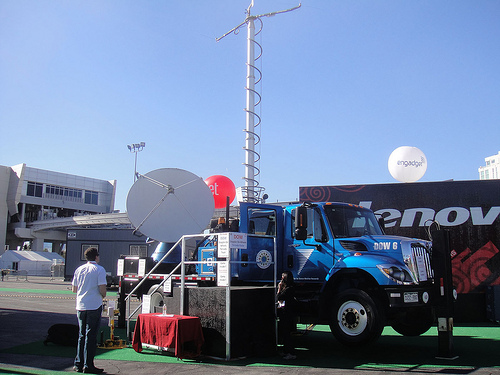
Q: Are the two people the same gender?
A: No, they are both male and female.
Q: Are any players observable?
A: No, there are no players.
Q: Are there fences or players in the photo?
A: No, there are no players or fences.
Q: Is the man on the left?
A: Yes, the man is on the left of the image.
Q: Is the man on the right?
A: No, the man is on the left of the image.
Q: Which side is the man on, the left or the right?
A: The man is on the left of the image.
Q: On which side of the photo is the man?
A: The man is on the left of the image.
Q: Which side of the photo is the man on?
A: The man is on the left of the image.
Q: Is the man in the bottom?
A: Yes, the man is in the bottom of the image.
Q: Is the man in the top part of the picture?
A: No, the man is in the bottom of the image.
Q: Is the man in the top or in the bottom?
A: The man is in the bottom of the image.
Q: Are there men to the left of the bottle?
A: Yes, there is a man to the left of the bottle.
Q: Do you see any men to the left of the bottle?
A: Yes, there is a man to the left of the bottle.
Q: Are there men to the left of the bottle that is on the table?
A: Yes, there is a man to the left of the bottle.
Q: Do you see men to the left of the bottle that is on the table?
A: Yes, there is a man to the left of the bottle.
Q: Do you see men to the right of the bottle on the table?
A: No, the man is to the left of the bottle.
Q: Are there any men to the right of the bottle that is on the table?
A: No, the man is to the left of the bottle.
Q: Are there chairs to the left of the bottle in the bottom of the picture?
A: No, there is a man to the left of the bottle.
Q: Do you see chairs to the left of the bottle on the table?
A: No, there is a man to the left of the bottle.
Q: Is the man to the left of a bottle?
A: Yes, the man is to the left of a bottle.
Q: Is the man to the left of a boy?
A: No, the man is to the left of a bottle.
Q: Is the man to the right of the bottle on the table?
A: No, the man is to the left of the bottle.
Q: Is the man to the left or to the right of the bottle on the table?
A: The man is to the left of the bottle.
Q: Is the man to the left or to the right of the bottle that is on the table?
A: The man is to the left of the bottle.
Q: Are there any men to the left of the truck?
A: Yes, there is a man to the left of the truck.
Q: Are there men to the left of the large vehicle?
A: Yes, there is a man to the left of the truck.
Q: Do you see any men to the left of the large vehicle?
A: Yes, there is a man to the left of the truck.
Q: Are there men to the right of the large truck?
A: No, the man is to the left of the truck.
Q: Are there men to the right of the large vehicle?
A: No, the man is to the left of the truck.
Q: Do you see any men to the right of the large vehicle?
A: No, the man is to the left of the truck.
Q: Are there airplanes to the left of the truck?
A: No, there is a man to the left of the truck.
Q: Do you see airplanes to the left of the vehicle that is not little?
A: No, there is a man to the left of the truck.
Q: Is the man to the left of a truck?
A: Yes, the man is to the left of a truck.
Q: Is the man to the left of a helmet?
A: No, the man is to the left of a truck.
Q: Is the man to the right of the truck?
A: No, the man is to the left of the truck.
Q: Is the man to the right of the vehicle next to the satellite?
A: No, the man is to the left of the truck.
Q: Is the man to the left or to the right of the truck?
A: The man is to the left of the truck.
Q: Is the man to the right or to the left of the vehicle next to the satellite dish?
A: The man is to the left of the truck.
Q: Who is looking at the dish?
A: The man is looking at the dish.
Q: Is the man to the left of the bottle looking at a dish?
A: Yes, the man is looking at a dish.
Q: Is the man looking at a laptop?
A: No, the man is looking at a dish.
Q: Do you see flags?
A: No, there are no flags.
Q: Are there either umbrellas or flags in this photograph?
A: No, there are no flags or umbrellas.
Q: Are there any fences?
A: No, there are no fences.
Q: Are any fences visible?
A: No, there are no fences.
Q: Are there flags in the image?
A: No, there are no flags.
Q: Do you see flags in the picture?
A: No, there are no flags.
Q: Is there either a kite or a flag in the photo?
A: No, there are no flags or kites.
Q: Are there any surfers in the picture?
A: No, there are no surfers.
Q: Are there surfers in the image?
A: No, there are no surfers.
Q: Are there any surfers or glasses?
A: No, there are no surfers or glasses.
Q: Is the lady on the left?
A: Yes, the lady is on the left of the image.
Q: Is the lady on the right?
A: No, the lady is on the left of the image.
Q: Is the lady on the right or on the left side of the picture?
A: The lady is on the left of the image.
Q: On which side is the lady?
A: The lady is on the left of the image.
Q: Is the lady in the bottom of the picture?
A: Yes, the lady is in the bottom of the image.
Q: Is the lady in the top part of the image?
A: No, the lady is in the bottom of the image.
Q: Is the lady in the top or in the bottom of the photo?
A: The lady is in the bottom of the image.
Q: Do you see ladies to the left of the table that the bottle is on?
A: Yes, there is a lady to the left of the table.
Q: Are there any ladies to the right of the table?
A: No, the lady is to the left of the table.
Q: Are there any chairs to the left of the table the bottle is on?
A: No, there is a lady to the left of the table.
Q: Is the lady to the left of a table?
A: Yes, the lady is to the left of a table.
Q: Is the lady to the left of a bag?
A: No, the lady is to the left of a table.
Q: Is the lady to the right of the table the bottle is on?
A: No, the lady is to the left of the table.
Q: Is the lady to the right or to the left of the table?
A: The lady is to the left of the table.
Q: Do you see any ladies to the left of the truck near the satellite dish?
A: Yes, there is a lady to the left of the truck.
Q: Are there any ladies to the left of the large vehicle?
A: Yes, there is a lady to the left of the truck.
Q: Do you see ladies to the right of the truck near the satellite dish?
A: No, the lady is to the left of the truck.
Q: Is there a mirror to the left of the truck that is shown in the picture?
A: No, there is a lady to the left of the truck.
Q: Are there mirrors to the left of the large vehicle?
A: No, there is a lady to the left of the truck.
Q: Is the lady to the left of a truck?
A: Yes, the lady is to the left of a truck.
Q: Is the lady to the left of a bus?
A: No, the lady is to the left of a truck.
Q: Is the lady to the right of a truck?
A: No, the lady is to the left of a truck.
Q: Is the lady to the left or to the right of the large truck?
A: The lady is to the left of the truck.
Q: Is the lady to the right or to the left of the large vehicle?
A: The lady is to the left of the truck.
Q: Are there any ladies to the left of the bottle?
A: Yes, there is a lady to the left of the bottle.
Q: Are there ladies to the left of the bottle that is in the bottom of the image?
A: Yes, there is a lady to the left of the bottle.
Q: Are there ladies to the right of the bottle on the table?
A: No, the lady is to the left of the bottle.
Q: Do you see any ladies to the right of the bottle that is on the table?
A: No, the lady is to the left of the bottle.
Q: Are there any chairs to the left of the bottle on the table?
A: No, there is a lady to the left of the bottle.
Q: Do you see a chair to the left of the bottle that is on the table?
A: No, there is a lady to the left of the bottle.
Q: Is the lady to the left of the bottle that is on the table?
A: Yes, the lady is to the left of the bottle.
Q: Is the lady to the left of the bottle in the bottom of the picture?
A: Yes, the lady is to the left of the bottle.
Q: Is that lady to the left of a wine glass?
A: No, the lady is to the left of the bottle.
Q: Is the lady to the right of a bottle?
A: No, the lady is to the left of a bottle.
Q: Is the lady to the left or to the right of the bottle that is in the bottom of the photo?
A: The lady is to the left of the bottle.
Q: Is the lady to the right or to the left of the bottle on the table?
A: The lady is to the left of the bottle.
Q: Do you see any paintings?
A: No, there are no paintings.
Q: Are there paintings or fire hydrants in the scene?
A: No, there are no paintings or fire hydrants.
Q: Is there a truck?
A: Yes, there is a truck.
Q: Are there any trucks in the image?
A: Yes, there is a truck.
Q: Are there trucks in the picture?
A: Yes, there is a truck.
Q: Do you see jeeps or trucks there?
A: Yes, there is a truck.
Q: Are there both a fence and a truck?
A: No, there is a truck but no fences.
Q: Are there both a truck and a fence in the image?
A: No, there is a truck but no fences.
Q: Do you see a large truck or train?
A: Yes, there is a large truck.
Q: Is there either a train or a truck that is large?
A: Yes, the truck is large.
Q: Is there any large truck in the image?
A: Yes, there is a large truck.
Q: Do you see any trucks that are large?
A: Yes, there is a truck that is large.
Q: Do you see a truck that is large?
A: Yes, there is a truck that is large.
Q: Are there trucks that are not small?
A: Yes, there is a large truck.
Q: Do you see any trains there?
A: No, there are no trains.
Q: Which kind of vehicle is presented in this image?
A: The vehicle is a truck.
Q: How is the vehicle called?
A: The vehicle is a truck.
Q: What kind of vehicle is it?
A: The vehicle is a truck.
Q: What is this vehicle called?
A: This is a truck.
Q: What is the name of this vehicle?
A: This is a truck.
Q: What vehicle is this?
A: This is a truck.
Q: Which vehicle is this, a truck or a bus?
A: This is a truck.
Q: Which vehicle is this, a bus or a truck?
A: This is a truck.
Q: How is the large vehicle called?
A: The vehicle is a truck.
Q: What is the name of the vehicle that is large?
A: The vehicle is a truck.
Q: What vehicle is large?
A: The vehicle is a truck.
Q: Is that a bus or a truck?
A: That is a truck.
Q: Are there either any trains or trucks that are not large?
A: No, there is a truck but it is large.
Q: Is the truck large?
A: Yes, the truck is large.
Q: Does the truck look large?
A: Yes, the truck is large.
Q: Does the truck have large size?
A: Yes, the truck is large.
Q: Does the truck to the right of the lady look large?
A: Yes, the truck is large.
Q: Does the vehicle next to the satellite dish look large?
A: Yes, the truck is large.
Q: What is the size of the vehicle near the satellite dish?
A: The truck is large.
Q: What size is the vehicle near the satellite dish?
A: The truck is large.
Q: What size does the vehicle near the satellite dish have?
A: The truck has large size.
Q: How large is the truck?
A: The truck is large.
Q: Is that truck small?
A: No, the truck is large.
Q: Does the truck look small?
A: No, the truck is large.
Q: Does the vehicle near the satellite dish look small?
A: No, the truck is large.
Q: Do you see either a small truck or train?
A: No, there is a truck but it is large.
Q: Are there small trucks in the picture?
A: No, there is a truck but it is large.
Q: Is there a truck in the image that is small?
A: No, there is a truck but it is large.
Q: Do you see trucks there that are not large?
A: No, there is a truck but it is large.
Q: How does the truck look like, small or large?
A: The truck is large.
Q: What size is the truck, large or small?
A: The truck is large.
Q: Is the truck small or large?
A: The truck is large.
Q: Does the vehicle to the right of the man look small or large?
A: The truck is large.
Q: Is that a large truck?
A: Yes, that is a large truck.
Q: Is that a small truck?
A: No, that is a large truck.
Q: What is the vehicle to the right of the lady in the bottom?
A: The vehicle is a truck.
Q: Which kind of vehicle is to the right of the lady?
A: The vehicle is a truck.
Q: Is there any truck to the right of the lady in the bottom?
A: Yes, there is a truck to the right of the lady.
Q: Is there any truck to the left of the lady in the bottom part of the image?
A: No, the truck is to the right of the lady.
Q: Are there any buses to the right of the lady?
A: No, there is a truck to the right of the lady.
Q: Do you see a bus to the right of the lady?
A: No, there is a truck to the right of the lady.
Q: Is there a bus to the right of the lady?
A: No, there is a truck to the right of the lady.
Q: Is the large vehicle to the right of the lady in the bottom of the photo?
A: Yes, the truck is to the right of the lady.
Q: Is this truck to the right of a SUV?
A: No, the truck is to the right of the lady.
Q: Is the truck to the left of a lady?
A: No, the truck is to the right of a lady.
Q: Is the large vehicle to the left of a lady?
A: No, the truck is to the right of a lady.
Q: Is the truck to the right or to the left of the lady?
A: The truck is to the right of the lady.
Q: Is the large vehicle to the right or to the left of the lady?
A: The truck is to the right of the lady.